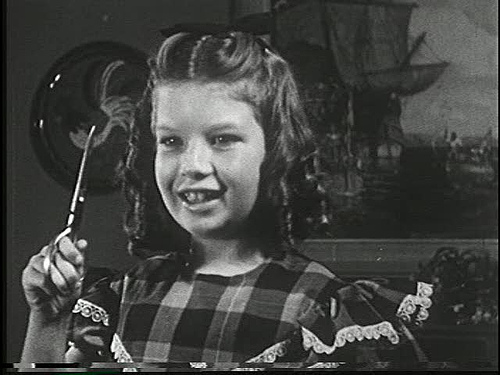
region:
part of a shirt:
[381, 293, 393, 302]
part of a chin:
[225, 220, 231, 231]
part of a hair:
[277, 199, 283, 225]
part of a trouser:
[336, 236, 351, 266]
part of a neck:
[266, 312, 274, 334]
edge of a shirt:
[262, 270, 273, 295]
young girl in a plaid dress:
[16, 27, 438, 366]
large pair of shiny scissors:
[40, 121, 110, 290]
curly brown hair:
[114, 22, 339, 259]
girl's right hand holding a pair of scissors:
[14, 120, 99, 374]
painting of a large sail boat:
[217, 1, 497, 273]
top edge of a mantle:
[296, 260, 495, 373]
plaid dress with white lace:
[50, 242, 435, 374]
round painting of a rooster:
[25, 30, 162, 202]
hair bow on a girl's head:
[147, 8, 278, 46]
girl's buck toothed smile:
[173, 185, 220, 216]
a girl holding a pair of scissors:
[13, 13, 392, 357]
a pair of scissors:
[35, 123, 110, 246]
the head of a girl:
[107, 28, 317, 259]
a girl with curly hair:
[117, 27, 347, 274]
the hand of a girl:
[16, 228, 95, 327]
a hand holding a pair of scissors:
[16, 115, 101, 325]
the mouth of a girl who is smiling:
[171, 179, 231, 215]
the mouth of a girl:
[171, 183, 230, 210]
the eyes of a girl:
[151, 123, 249, 158]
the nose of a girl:
[174, 158, 219, 182]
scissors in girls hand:
[22, 103, 102, 340]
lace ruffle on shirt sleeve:
[286, 248, 433, 371]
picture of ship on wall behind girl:
[288, 7, 452, 199]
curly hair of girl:
[253, 110, 360, 259]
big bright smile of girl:
[141, 148, 269, 233]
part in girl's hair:
[149, 22, 252, 99]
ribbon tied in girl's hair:
[151, 3, 306, 80]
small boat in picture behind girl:
[388, 90, 495, 200]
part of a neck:
[233, 263, 240, 273]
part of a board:
[377, 175, 392, 208]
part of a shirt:
[265, 311, 289, 353]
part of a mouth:
[206, 198, 219, 219]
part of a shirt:
[298, 303, 313, 322]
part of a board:
[366, 243, 382, 286]